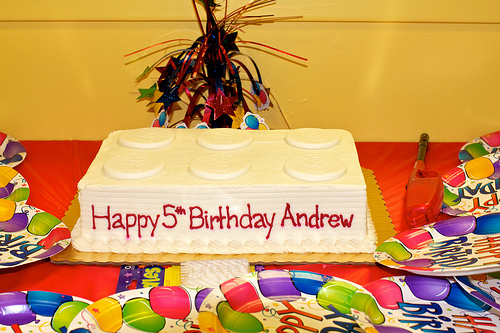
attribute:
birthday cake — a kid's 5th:
[71, 120, 381, 260]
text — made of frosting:
[86, 197, 356, 244]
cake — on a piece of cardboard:
[43, 120, 402, 267]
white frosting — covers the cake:
[67, 126, 377, 255]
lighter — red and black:
[401, 125, 446, 227]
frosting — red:
[88, 198, 358, 237]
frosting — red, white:
[86, 175, 366, 247]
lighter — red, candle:
[395, 128, 448, 234]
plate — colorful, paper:
[0, 198, 77, 270]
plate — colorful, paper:
[61, 280, 201, 330]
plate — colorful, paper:
[357, 269, 499, 331]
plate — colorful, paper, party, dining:
[373, 214, 498, 278]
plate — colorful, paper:
[437, 154, 499, 221]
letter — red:
[339, 210, 356, 229]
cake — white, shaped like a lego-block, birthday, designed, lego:
[77, 126, 380, 259]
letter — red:
[328, 213, 342, 229]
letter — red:
[317, 210, 331, 230]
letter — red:
[309, 200, 321, 230]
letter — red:
[294, 209, 308, 229]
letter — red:
[277, 195, 298, 227]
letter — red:
[259, 209, 276, 242]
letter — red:
[246, 203, 266, 232]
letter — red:
[239, 198, 253, 232]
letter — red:
[224, 202, 238, 229]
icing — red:
[84, 200, 357, 236]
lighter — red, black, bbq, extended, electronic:
[400, 130, 448, 230]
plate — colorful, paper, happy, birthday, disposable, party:
[199, 265, 388, 331]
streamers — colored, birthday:
[126, 0, 319, 130]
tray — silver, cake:
[46, 162, 406, 264]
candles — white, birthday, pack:
[113, 259, 261, 296]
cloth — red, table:
[19, 141, 466, 303]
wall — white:
[5, 3, 496, 137]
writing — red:
[86, 203, 357, 232]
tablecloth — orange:
[12, 140, 99, 214]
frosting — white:
[72, 127, 373, 251]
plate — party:
[67, 287, 218, 330]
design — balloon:
[68, 288, 221, 328]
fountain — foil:
[122, 0, 310, 126]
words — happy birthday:
[425, 235, 499, 265]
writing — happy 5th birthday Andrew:
[86, 199, 358, 239]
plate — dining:
[438, 151, 498, 219]